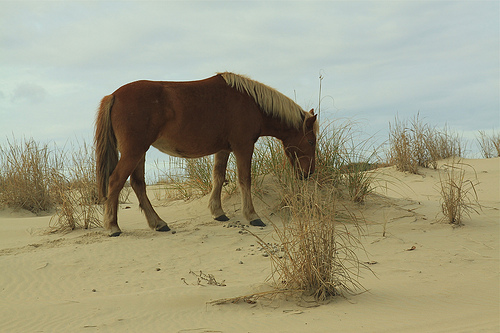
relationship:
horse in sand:
[92, 70, 318, 237] [0, 152, 500, 332]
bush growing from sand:
[430, 153, 486, 229] [0, 152, 500, 332]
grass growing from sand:
[0, 130, 68, 217] [0, 152, 500, 332]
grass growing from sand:
[0, 140, 61, 212] [3, 225, 261, 329]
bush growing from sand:
[42, 164, 105, 236] [86, 197, 431, 288]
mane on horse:
[215, 70, 320, 136] [84, 67, 324, 240]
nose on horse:
[302, 167, 313, 182] [84, 67, 324, 240]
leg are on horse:
[104, 144, 152, 237] [84, 67, 324, 240]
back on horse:
[117, 71, 270, 101] [84, 67, 324, 240]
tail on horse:
[91, 94, 113, 209] [92, 70, 318, 237]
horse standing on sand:
[84, 67, 324, 240] [0, 152, 500, 332]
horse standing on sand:
[92, 70, 318, 237] [0, 152, 500, 332]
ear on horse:
[300, 110, 324, 133] [84, 67, 324, 240]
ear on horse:
[306, 105, 319, 119] [84, 67, 324, 240]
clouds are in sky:
[22, 14, 124, 69] [11, 7, 498, 108]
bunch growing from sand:
[208, 151, 380, 307] [0, 152, 500, 332]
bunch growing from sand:
[208, 151, 380, 307] [349, 242, 496, 326]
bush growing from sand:
[372, 109, 471, 176] [200, 283, 487, 329]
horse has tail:
[92, 70, 318, 237] [74, 84, 126, 198]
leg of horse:
[102, 144, 138, 240] [70, 82, 360, 284]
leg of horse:
[127, 163, 179, 235] [70, 82, 360, 284]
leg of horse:
[206, 144, 230, 225] [70, 82, 360, 284]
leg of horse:
[229, 138, 274, 228] [70, 82, 360, 284]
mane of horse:
[215, 70, 320, 136] [40, 49, 388, 248]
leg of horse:
[104, 144, 152, 237] [73, 64, 374, 299]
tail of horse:
[94, 93, 111, 203] [84, 67, 324, 240]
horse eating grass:
[92, 70, 318, 237] [302, 172, 388, 252]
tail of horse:
[91, 94, 113, 209] [84, 67, 324, 240]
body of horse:
[107, 76, 275, 221] [84, 67, 324, 240]